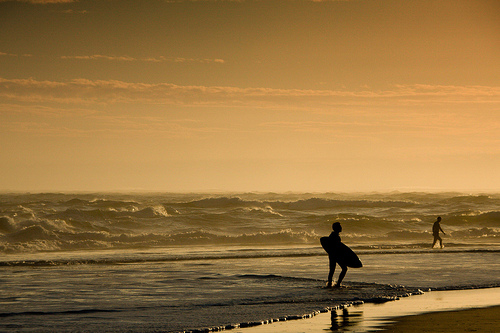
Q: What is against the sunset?
A: Clouds.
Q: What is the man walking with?
A: Surfboard.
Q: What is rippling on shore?
A: Water.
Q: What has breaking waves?
A: Rough waters.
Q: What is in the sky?
A: Clouds.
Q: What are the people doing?
A: Walking in water.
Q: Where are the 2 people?
A: On beach.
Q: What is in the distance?
A: Waves.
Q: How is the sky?
A: Cloudy.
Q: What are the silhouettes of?
A: 2 People.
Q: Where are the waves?
A: On water.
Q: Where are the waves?
A: In ocean.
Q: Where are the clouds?
A: Sky.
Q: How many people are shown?
A: Two.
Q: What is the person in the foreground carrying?
A: Surfboard.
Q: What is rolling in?
A: Waves.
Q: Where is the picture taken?
A: At the beach.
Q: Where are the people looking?
A: Away from the camera.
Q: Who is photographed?
A: Surfers.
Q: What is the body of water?
A: The ocean.